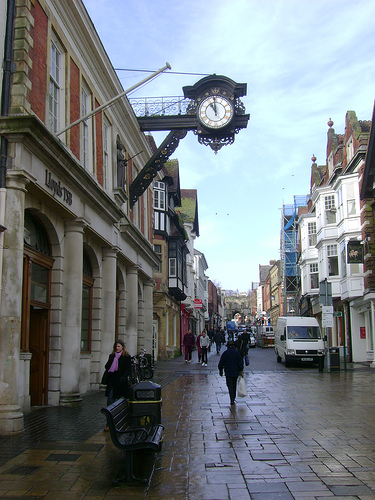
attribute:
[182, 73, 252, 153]
clock — white, indicating, suspended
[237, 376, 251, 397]
bag — plastic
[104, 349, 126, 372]
scarf — purple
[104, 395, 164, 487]
bench — edgy, empty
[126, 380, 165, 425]
bin — cornered, trash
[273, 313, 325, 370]
truck — white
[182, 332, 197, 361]
clothing — red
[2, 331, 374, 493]
pavenment — brick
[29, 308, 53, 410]
door — wooden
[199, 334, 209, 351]
shirt — white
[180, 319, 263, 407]
people — walking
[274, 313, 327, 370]
van — white, parked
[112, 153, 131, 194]
window — dark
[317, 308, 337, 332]
sign — back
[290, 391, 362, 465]
floor — part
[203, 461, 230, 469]
crack — edge, part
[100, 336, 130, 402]
woman — walking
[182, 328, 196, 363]
man — walking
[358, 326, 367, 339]
sign — red